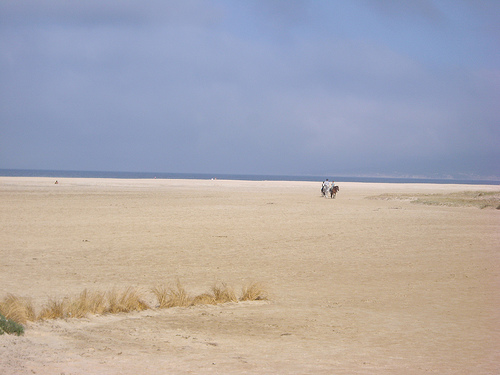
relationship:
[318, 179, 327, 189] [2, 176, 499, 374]
person walking on beach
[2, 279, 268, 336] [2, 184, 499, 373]
grass growing in sand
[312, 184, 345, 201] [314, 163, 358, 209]
people riding horses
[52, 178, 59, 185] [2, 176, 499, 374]
speck on beach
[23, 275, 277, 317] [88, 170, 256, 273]
plants growing on beach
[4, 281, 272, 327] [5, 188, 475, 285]
grass growing on beach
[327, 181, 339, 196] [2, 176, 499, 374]
horse walking on beach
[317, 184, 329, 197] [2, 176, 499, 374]
horse walking on beach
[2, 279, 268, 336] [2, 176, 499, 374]
grass on beach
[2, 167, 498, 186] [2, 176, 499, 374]
water beyond beach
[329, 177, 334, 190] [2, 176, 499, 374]
person on beach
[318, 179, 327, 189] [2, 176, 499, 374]
person on beach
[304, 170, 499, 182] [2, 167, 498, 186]
land beyond water